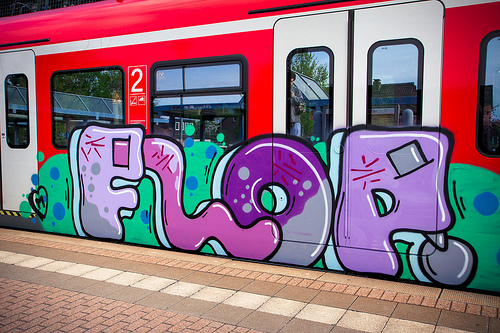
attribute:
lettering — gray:
[268, 184, 338, 271]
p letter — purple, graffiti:
[334, 119, 460, 280]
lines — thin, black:
[0, 33, 56, 49]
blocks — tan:
[181, 285, 296, 313]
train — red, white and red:
[0, 0, 500, 295]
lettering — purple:
[77, 120, 480, 290]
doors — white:
[268, 0, 448, 259]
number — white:
[129, 66, 142, 95]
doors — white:
[272, 4, 448, 142]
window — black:
[1, 32, 499, 159]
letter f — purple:
[64, 117, 147, 246]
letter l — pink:
[112, 135, 288, 265]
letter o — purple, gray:
[206, 128, 333, 271]